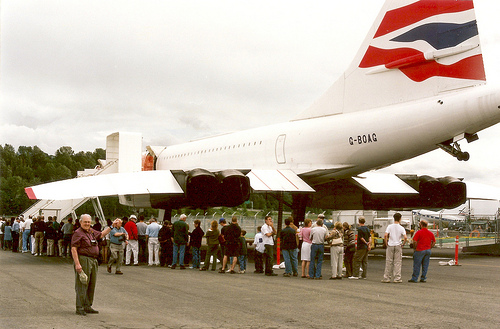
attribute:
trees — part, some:
[0, 143, 333, 214]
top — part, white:
[382, 220, 409, 247]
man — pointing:
[64, 207, 104, 316]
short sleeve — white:
[60, 224, 87, 252]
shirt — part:
[70, 225, 102, 256]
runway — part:
[25, 254, 497, 318]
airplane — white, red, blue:
[27, 0, 498, 215]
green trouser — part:
[56, 251, 147, 300]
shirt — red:
[410, 225, 437, 253]